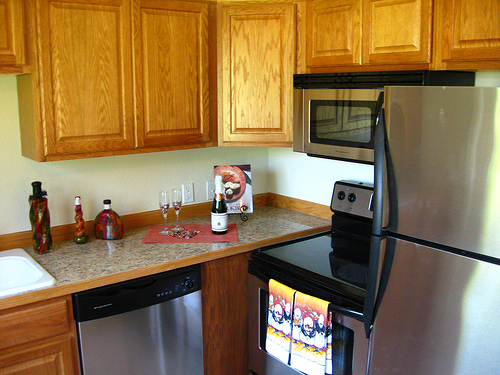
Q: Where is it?
A: This is at the kitchen.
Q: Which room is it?
A: It is a kitchen.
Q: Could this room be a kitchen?
A: Yes, it is a kitchen.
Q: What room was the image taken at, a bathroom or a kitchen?
A: It was taken at a kitchen.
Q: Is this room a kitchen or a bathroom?
A: It is a kitchen.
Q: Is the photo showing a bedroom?
A: No, the picture is showing a kitchen.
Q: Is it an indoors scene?
A: Yes, it is indoors.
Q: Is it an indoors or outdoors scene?
A: It is indoors.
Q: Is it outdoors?
A: No, it is indoors.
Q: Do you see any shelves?
A: No, there are no shelves.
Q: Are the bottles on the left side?
A: Yes, the bottles are on the left of the image.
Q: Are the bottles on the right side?
A: No, the bottles are on the left of the image.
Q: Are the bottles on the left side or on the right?
A: The bottles are on the left of the image.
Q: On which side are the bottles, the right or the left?
A: The bottles are on the left of the image.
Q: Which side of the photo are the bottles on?
A: The bottles are on the left of the image.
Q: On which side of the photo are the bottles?
A: The bottles are on the left of the image.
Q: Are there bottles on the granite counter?
A: Yes, there are bottles on the counter.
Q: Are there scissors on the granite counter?
A: No, there are bottles on the counter.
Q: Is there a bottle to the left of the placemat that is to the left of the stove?
A: Yes, there are bottles to the left of the place mat.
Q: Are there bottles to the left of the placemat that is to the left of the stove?
A: Yes, there are bottles to the left of the place mat.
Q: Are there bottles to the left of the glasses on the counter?
A: Yes, there are bottles to the left of the glasses.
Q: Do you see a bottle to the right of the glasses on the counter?
A: No, the bottles are to the left of the glasses.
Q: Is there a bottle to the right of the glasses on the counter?
A: No, the bottles are to the left of the glasses.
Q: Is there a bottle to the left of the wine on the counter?
A: Yes, there are bottles to the left of the wine.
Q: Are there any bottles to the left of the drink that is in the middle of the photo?
A: Yes, there are bottles to the left of the wine.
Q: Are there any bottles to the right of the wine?
A: No, the bottles are to the left of the wine.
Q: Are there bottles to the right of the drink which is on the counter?
A: No, the bottles are to the left of the wine.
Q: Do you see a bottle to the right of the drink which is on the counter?
A: No, the bottles are to the left of the wine.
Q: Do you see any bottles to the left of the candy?
A: Yes, there are bottles to the left of the candy.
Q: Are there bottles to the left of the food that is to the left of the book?
A: Yes, there are bottles to the left of the candy.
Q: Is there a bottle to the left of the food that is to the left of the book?
A: Yes, there are bottles to the left of the candy.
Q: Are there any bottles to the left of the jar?
A: Yes, there are bottles to the left of the jar.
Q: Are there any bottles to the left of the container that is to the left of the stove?
A: Yes, there are bottles to the left of the jar.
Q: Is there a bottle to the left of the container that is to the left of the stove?
A: Yes, there are bottles to the left of the jar.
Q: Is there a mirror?
A: No, there are no mirrors.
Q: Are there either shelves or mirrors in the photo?
A: No, there are no mirrors or shelves.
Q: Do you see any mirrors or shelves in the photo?
A: No, there are no mirrors or shelves.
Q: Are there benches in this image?
A: No, there are no benches.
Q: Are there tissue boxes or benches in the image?
A: No, there are no benches or tissue boxes.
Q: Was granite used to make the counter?
A: Yes, the counter is made of granite.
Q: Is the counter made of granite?
A: Yes, the counter is made of granite.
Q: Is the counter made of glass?
A: No, the counter is made of granite.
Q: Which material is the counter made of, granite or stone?
A: The counter is made of granite.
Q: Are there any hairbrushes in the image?
A: No, there are no hairbrushes.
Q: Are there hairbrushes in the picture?
A: No, there are no hairbrushes.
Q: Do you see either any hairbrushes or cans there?
A: No, there are no hairbrushes or cans.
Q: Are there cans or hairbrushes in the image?
A: No, there are no hairbrushes or cans.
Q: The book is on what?
A: The book is on the counter.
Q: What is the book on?
A: The book is on the counter.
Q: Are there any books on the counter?
A: Yes, there is a book on the counter.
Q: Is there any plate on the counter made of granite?
A: No, there is a book on the counter.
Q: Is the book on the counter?
A: Yes, the book is on the counter.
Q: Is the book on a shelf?
A: No, the book is on the counter.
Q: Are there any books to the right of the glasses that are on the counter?
A: Yes, there is a book to the right of the glasses.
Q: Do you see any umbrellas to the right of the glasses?
A: No, there is a book to the right of the glasses.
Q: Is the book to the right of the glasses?
A: Yes, the book is to the right of the glasses.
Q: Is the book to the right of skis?
A: No, the book is to the right of the glasses.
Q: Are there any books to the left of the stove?
A: Yes, there is a book to the left of the stove.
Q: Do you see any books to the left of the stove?
A: Yes, there is a book to the left of the stove.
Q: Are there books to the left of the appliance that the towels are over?
A: Yes, there is a book to the left of the stove.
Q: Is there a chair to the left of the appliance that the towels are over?
A: No, there is a book to the left of the stove.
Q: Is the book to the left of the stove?
A: Yes, the book is to the left of the stove.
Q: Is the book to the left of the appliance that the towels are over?
A: Yes, the book is to the left of the stove.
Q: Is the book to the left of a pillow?
A: No, the book is to the left of the stove.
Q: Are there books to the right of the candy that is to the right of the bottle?
A: Yes, there is a book to the right of the candy.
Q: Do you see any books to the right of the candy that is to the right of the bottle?
A: Yes, there is a book to the right of the candy.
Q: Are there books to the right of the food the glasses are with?
A: Yes, there is a book to the right of the candy.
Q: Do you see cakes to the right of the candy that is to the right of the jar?
A: No, there is a book to the right of the candy.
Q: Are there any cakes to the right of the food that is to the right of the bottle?
A: No, there is a book to the right of the candy.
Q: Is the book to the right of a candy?
A: Yes, the book is to the right of a candy.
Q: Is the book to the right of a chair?
A: No, the book is to the right of a candy.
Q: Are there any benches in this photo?
A: No, there are no benches.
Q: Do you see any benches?
A: No, there are no benches.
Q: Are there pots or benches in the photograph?
A: No, there are no benches or pots.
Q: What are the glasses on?
A: The glasses are on the counter.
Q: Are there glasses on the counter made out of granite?
A: Yes, there are glasses on the counter.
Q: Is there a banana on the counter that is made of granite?
A: No, there are glasses on the counter.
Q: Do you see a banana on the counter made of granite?
A: No, there are glasses on the counter.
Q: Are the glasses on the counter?
A: Yes, the glasses are on the counter.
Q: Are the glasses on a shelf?
A: No, the glasses are on the counter.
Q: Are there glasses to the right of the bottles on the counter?
A: Yes, there are glasses to the right of the bottles.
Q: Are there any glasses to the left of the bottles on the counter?
A: No, the glasses are to the right of the bottles.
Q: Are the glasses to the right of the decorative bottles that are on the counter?
A: Yes, the glasses are to the right of the bottles.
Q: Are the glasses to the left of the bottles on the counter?
A: No, the glasses are to the right of the bottles.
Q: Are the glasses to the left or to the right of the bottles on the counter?
A: The glasses are to the right of the bottles.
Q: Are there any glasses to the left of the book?
A: Yes, there are glasses to the left of the book.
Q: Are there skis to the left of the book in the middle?
A: No, there are glasses to the left of the book.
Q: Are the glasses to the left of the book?
A: Yes, the glasses are to the left of the book.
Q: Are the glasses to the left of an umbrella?
A: No, the glasses are to the left of the book.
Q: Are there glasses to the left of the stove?
A: Yes, there are glasses to the left of the stove.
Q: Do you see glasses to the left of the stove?
A: Yes, there are glasses to the left of the stove.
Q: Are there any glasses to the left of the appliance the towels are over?
A: Yes, there are glasses to the left of the stove.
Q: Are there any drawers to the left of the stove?
A: No, there are glasses to the left of the stove.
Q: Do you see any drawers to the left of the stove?
A: No, there are glasses to the left of the stove.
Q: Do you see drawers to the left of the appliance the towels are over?
A: No, there are glasses to the left of the stove.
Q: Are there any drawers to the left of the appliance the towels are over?
A: No, there are glasses to the left of the stove.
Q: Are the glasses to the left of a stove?
A: Yes, the glasses are to the left of a stove.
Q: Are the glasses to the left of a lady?
A: No, the glasses are to the left of a stove.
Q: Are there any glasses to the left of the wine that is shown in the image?
A: Yes, there are glasses to the left of the wine.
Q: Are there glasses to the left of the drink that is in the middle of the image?
A: Yes, there are glasses to the left of the wine.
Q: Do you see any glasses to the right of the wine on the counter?
A: No, the glasses are to the left of the wine.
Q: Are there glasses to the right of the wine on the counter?
A: No, the glasses are to the left of the wine.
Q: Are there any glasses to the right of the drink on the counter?
A: No, the glasses are to the left of the wine.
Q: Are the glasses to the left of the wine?
A: Yes, the glasses are to the left of the wine.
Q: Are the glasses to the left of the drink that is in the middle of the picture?
A: Yes, the glasses are to the left of the wine.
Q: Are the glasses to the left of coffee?
A: No, the glasses are to the left of the wine.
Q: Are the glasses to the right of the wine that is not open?
A: No, the glasses are to the left of the wine.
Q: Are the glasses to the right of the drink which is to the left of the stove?
A: No, the glasses are to the left of the wine.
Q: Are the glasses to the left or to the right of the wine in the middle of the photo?
A: The glasses are to the left of the wine.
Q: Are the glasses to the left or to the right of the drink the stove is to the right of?
A: The glasses are to the left of the wine.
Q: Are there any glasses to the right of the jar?
A: Yes, there are glasses to the right of the jar.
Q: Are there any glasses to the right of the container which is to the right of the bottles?
A: Yes, there are glasses to the right of the jar.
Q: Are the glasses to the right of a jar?
A: Yes, the glasses are to the right of a jar.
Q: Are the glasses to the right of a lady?
A: No, the glasses are to the right of a jar.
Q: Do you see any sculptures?
A: No, there are no sculptures.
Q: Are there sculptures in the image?
A: No, there are no sculptures.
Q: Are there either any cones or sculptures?
A: No, there are no sculptures or cones.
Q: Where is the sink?
A: The sink is in the kitchen.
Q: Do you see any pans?
A: No, there are no pans.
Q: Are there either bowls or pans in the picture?
A: No, there are no pans or bowls.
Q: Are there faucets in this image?
A: No, there are no faucets.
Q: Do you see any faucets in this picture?
A: No, there are no faucets.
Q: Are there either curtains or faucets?
A: No, there are no faucets or curtains.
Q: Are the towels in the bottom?
A: Yes, the towels are in the bottom of the image.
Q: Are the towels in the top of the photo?
A: No, the towels are in the bottom of the image.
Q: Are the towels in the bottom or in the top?
A: The towels are in the bottom of the image.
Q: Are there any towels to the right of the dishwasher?
A: Yes, there are towels to the right of the dishwasher.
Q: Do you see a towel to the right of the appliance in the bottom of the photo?
A: Yes, there are towels to the right of the dishwasher.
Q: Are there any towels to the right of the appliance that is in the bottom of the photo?
A: Yes, there are towels to the right of the dishwasher.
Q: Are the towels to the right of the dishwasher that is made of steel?
A: Yes, the towels are to the right of the dish washer.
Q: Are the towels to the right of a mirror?
A: No, the towels are to the right of the dish washer.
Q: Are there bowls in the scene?
A: No, there are no bowls.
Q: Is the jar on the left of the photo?
A: Yes, the jar is on the left of the image.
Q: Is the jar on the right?
A: No, the jar is on the left of the image.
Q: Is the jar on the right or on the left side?
A: The jar is on the left of the image.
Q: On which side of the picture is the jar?
A: The jar is on the left of the image.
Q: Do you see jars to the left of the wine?
A: Yes, there is a jar to the left of the wine.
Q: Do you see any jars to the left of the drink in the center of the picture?
A: Yes, there is a jar to the left of the wine.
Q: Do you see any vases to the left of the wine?
A: No, there is a jar to the left of the wine.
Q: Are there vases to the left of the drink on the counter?
A: No, there is a jar to the left of the wine.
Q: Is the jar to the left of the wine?
A: Yes, the jar is to the left of the wine.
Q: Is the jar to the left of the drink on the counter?
A: Yes, the jar is to the left of the wine.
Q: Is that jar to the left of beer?
A: No, the jar is to the left of the wine.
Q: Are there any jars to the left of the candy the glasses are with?
A: Yes, there is a jar to the left of the candy.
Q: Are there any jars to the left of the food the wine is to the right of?
A: Yes, there is a jar to the left of the candy.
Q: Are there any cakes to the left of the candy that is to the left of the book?
A: No, there is a jar to the left of the candy.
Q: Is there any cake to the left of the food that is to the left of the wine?
A: No, there is a jar to the left of the candy.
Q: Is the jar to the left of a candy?
A: Yes, the jar is to the left of a candy.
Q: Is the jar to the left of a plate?
A: No, the jar is to the left of a candy.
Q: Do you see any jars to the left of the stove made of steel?
A: Yes, there is a jar to the left of the stove.